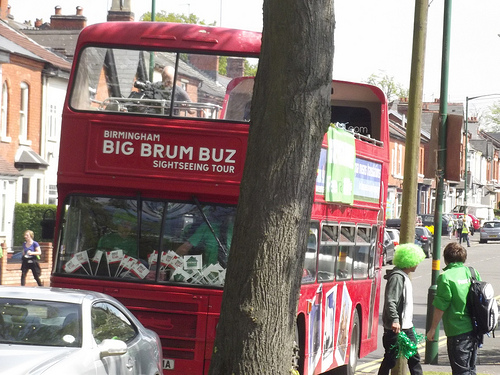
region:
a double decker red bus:
[51, 19, 386, 372]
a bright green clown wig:
[390, 244, 422, 269]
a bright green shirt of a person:
[432, 266, 482, 341]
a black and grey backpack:
[458, 278, 498, 335]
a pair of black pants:
[377, 326, 420, 372]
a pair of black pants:
[445, 327, 481, 373]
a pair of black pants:
[17, 260, 44, 282]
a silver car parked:
[0, 285, 162, 373]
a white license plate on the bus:
[163, 356, 173, 368]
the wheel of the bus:
[345, 301, 361, 371]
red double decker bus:
[65, 10, 432, 359]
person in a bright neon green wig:
[378, 241, 425, 300]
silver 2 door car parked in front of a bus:
[1, 270, 170, 373]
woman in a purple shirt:
[13, 225, 62, 287]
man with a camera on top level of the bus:
[127, 60, 193, 116]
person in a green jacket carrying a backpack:
[424, 235, 499, 349]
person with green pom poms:
[377, 316, 427, 366]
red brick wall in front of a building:
[6, 237, 58, 292]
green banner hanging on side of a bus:
[320, 120, 362, 214]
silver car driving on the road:
[483, 213, 498, 251]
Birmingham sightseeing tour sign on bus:
[66, 110, 253, 181]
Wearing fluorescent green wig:
[378, 222, 431, 305]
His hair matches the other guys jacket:
[375, 233, 497, 368]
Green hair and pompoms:
[367, 234, 434, 374]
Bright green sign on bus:
[326, 125, 383, 232]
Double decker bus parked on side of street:
[48, 40, 449, 372]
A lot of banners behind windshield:
[63, 235, 238, 288]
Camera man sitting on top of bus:
[121, 58, 211, 113]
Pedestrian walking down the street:
[8, 214, 63, 294]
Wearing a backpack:
[428, 235, 497, 359]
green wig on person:
[386, 242, 416, 267]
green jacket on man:
[424, 262, 481, 338]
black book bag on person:
[466, 274, 498, 336]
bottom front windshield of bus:
[68, 187, 228, 283]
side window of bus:
[316, 226, 336, 279]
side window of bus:
[338, 230, 353, 281]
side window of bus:
[356, 228, 370, 280]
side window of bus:
[304, 227, 318, 285]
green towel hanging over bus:
[313, 132, 353, 204]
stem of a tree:
[296, 265, 300, 275]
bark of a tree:
[266, 272, 276, 369]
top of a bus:
[346, 137, 368, 174]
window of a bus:
[175, 230, 197, 250]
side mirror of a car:
[113, 349, 122, 356]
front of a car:
[67, 315, 82, 320]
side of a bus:
[321, 295, 339, 322]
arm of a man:
[386, 281, 390, 324]